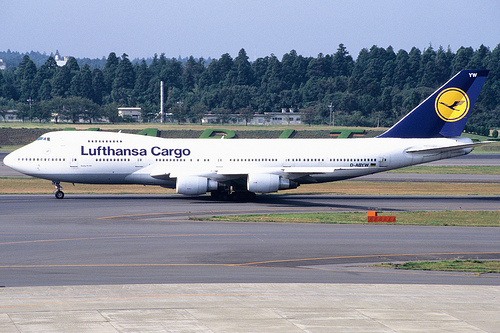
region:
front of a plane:
[9, 125, 87, 179]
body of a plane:
[95, 122, 292, 193]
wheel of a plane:
[49, 189, 79, 210]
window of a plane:
[29, 133, 59, 148]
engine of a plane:
[166, 165, 224, 206]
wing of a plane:
[139, 136, 376, 183]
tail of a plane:
[340, 126, 491, 187]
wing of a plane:
[406, 133, 470, 168]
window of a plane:
[219, 149, 394, 163]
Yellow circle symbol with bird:
[433, 87, 473, 132]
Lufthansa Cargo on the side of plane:
[76, 142, 194, 157]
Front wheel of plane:
[52, 188, 68, 202]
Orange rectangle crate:
[362, 207, 399, 225]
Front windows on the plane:
[35, 134, 53, 146]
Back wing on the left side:
[406, 139, 498, 158]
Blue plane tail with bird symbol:
[380, 64, 493, 139]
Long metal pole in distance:
[152, 77, 167, 122]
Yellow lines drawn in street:
[0, 222, 495, 274]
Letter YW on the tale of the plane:
[465, 69, 479, 86]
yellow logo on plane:
[429, 84, 471, 126]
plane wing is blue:
[369, 54, 488, 137]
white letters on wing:
[463, 67, 481, 79]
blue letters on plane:
[75, 140, 192, 161]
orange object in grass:
[361, 204, 401, 224]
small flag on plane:
[366, 157, 380, 168]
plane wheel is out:
[51, 192, 68, 203]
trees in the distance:
[2, 24, 499, 138]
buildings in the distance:
[1, 104, 338, 131]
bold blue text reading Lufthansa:
[78, 143, 149, 155]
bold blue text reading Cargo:
[150, 145, 193, 158]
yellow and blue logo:
[431, 85, 469, 123]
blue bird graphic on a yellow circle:
[435, 86, 472, 122]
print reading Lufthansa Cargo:
[78, 143, 196, 158]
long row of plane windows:
[18, 156, 384, 162]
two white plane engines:
[175, 172, 300, 198]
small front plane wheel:
[51, 190, 66, 199]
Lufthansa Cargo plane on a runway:
[1, 67, 498, 202]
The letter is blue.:
[87, 144, 99, 159]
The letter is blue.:
[105, 143, 115, 158]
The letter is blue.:
[101, 143, 108, 159]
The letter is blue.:
[95, 143, 102, 158]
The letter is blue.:
[148, 143, 163, 158]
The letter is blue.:
[114, 145, 125, 157]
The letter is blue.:
[121, 144, 133, 158]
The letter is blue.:
[129, 146, 141, 157]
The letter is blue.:
[138, 146, 149, 157]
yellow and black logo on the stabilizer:
[435, 85, 470, 121]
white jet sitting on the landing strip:
[2, 70, 472, 200]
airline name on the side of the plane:
[78, 142, 193, 159]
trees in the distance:
[16, 41, 498, 140]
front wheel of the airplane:
[51, 191, 63, 202]